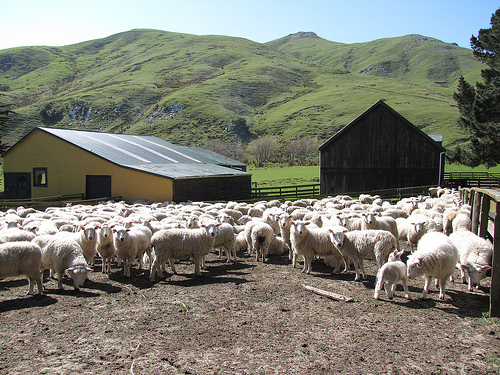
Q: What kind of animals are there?
A: Sheep.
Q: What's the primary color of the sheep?
A: White.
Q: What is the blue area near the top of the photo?
A: The sky.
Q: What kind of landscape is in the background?
A: Hills.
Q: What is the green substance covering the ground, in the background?
A: Grass.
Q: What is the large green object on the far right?
A: A tree.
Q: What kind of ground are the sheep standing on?
A: Dirt.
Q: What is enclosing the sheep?
A: A fence.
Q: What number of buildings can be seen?
A: Two.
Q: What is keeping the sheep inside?
A: A fence.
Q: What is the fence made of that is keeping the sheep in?
A: Wood.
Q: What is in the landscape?
A: Green hills.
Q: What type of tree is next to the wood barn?
A: An evergreen.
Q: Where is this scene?
A: Farm.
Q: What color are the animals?
A: White.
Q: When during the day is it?
A: Morning.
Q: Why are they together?
A: A herd.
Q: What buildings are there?
A: Barns.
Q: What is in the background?
A: Mountains.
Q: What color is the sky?
A: Blue.